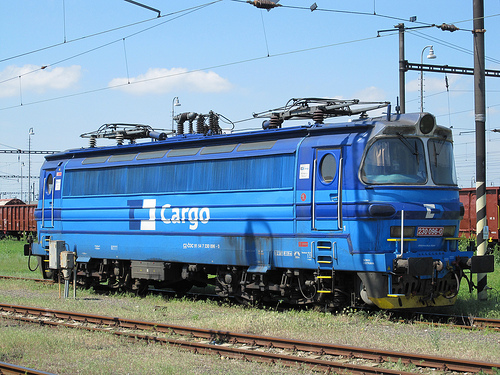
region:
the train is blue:
[20, 93, 493, 324]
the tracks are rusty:
[1, 298, 492, 374]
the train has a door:
[305, 141, 348, 237]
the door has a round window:
[317, 150, 340, 186]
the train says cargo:
[159, 200, 212, 230]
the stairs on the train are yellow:
[306, 236, 341, 302]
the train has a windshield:
[360, 127, 464, 193]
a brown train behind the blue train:
[1, 200, 41, 242]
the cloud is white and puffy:
[105, 58, 237, 106]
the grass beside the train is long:
[133, 275, 498, 368]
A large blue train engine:
[26, 96, 476, 319]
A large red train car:
[458, 184, 498, 241]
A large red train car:
[2, 202, 38, 237]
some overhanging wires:
[1, 0, 498, 120]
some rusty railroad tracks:
[1, 302, 498, 374]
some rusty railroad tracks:
[1, 274, 499, 331]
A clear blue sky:
[2, 0, 499, 201]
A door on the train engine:
[310, 145, 342, 227]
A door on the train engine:
[41, 167, 58, 232]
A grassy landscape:
[1, 239, 496, 373]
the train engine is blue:
[15, 86, 489, 316]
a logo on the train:
[127, 192, 212, 238]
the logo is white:
[121, 194, 211, 237]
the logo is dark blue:
[122, 192, 224, 230]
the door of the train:
[304, 149, 349, 230]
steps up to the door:
[299, 232, 351, 312]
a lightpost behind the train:
[411, 34, 440, 112]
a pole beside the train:
[445, 2, 495, 303]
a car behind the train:
[0, 203, 37, 243]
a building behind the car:
[0, 184, 32, 204]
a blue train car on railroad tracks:
[23, 93, 475, 310]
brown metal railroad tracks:
[1, 302, 498, 372]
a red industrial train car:
[0, 203, 36, 243]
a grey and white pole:
[471, 1, 489, 301]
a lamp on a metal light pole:
[417, 43, 438, 110]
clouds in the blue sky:
[0, 63, 242, 95]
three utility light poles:
[26, 43, 438, 203]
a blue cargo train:
[23, 96, 495, 310]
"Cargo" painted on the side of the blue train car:
[159, 202, 211, 231]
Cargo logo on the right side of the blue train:
[125, 195, 210, 231]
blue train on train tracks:
[25, 105, 475, 315]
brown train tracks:
[3, 297, 495, 372]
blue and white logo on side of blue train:
[120, 196, 160, 236]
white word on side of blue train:
[158, 201, 213, 230]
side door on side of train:
[304, 141, 350, 235]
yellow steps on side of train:
[301, 235, 340, 302]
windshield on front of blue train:
[358, 128, 459, 198]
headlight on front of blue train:
[409, 104, 439, 141]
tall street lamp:
[412, 38, 441, 111]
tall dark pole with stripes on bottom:
[459, 2, 495, 306]